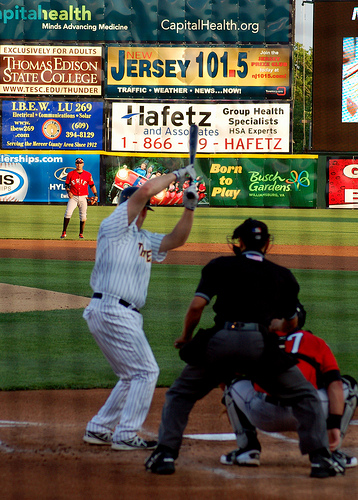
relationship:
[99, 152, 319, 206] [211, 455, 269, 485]
sign on side of fence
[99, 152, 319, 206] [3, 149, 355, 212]
sign on side of fence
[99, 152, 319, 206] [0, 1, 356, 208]
sign on side of fence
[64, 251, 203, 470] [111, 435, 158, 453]
player wearing shoes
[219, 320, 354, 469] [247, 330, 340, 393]
player wearing red uniform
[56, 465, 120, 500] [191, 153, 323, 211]
born to play busch gardens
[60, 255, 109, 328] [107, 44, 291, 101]
new jersey  banner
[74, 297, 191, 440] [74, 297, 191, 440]
pants wearing stripe pants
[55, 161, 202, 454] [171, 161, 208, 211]
man wearing white gloves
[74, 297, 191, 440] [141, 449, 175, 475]
pants wearing black shoes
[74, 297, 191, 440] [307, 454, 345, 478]
pants wearing black shoes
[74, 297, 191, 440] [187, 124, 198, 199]
pants holding bat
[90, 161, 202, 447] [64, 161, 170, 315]
man wearing shirt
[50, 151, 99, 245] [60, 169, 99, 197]
man wearing red shirt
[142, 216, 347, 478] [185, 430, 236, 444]
umpire behind home plate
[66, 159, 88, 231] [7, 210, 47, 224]
infielder on grass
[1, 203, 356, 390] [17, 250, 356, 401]
grass on infield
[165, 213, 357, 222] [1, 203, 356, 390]
shadow on grass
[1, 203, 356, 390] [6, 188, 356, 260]
grass in outfield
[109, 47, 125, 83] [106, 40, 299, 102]
letter on sign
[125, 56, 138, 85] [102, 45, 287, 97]
letter on sign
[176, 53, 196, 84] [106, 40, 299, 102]
letter on sign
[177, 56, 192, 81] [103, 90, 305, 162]
letter on sign